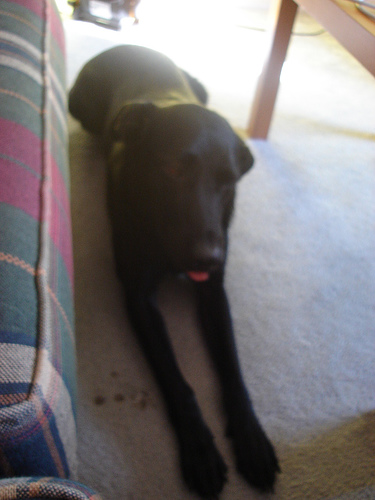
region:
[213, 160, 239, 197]
right eye of dog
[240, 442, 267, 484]
right paw of dog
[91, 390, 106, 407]
red stain on carpet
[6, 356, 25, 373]
beige stripe on couch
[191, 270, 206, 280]
dogs tounge in mouth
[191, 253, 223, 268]
dogs nose is black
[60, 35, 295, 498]
black dog lying on the carpet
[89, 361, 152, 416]
brown stains on the carpet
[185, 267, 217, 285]
pink tongue of the black dog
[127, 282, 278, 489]
long black legs of the dog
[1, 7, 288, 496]
dog next to the couch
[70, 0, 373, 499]
dog next to the table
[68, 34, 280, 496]
an all black colored dog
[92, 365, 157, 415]
stains next to the dog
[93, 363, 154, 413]
stains next to the black dog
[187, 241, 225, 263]
black nose of the black dog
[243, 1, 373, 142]
leg of table on the carpet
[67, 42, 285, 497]
big black dog laying on the carpet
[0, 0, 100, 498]
plaid fabric on a chair cushion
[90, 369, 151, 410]
spots on the carpet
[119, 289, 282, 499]
dog's legs stretched out in front of him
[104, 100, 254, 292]
head of a dog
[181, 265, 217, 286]
dog's tongue sticking out of mouth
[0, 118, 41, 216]
pink stripe on chair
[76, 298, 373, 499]
brown trim on the carpet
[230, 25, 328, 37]
electrical cord on the floor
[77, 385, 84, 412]
part of a chair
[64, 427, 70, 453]
edge of a chair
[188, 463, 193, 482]
part of a floor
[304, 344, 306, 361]
edge of a floor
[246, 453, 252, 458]
edge of a leg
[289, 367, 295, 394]
part of a floor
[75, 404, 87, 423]
part of a chair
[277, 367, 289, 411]
edge of a mat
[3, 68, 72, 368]
couch is plaid pattern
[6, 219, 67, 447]
stripes on the couch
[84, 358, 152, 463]
spots on the floor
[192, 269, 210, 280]
the tongue is red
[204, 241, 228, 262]
the nose is black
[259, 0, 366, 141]
the table is wooden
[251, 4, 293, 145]
table leg is wooden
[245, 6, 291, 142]
table leg is brown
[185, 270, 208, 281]
Red tip of a black dog's tongue.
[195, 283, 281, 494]
A black dog's left arm.